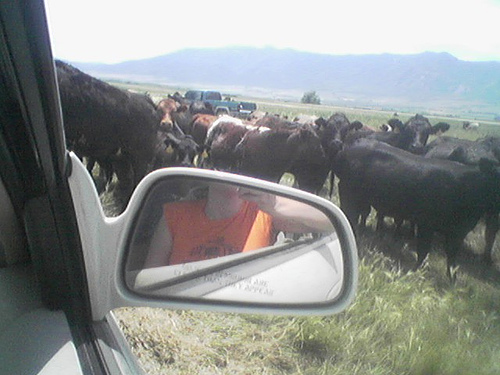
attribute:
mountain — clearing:
[94, 45, 499, 123]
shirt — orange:
[161, 197, 271, 264]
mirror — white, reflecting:
[112, 163, 360, 314]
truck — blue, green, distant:
[1, 0, 147, 374]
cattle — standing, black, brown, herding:
[50, 56, 499, 288]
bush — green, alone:
[302, 90, 320, 103]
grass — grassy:
[104, 194, 499, 372]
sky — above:
[44, 1, 499, 117]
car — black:
[3, 1, 355, 372]